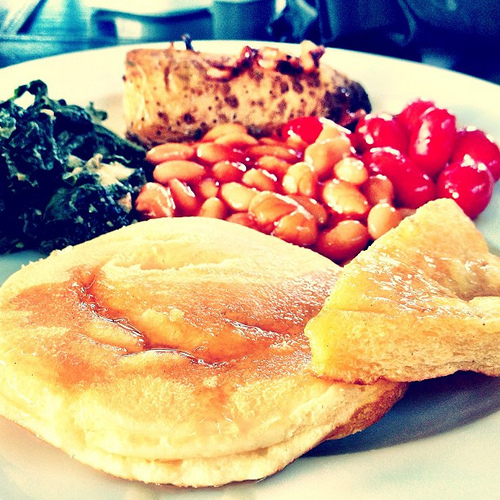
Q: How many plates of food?
A: 1.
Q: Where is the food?
A: On a plate.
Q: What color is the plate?
A: White.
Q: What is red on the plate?
A: Beans.